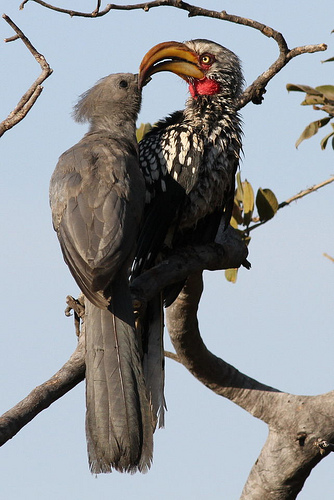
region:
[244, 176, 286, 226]
leaf on a tree branch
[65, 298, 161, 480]
bird tail feather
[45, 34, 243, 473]
two birds together in a tree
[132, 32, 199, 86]
yellow bird beak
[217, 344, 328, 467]
brown tree bark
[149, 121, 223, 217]
black and white spotted bird feathers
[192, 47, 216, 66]
yellow bird eye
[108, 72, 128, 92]
black bird eye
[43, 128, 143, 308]
grey bird wings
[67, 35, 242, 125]
two birds touching beaks in a tree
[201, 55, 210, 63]
yellow eye on bigger bird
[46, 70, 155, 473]
grey baby bird with long tail feathers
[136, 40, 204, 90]
crooked orange beak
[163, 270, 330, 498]
large tree branch on the right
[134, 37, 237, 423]
black and white large bird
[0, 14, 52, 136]
small crooked branch in the upper left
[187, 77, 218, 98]
red crop on larger bird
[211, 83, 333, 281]
branch with leaves on the right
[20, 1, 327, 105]
long, skinny tree branch on the top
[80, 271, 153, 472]
long grey tail feathers of baby bird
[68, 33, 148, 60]
the sky is blue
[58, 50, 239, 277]
the birds are perched on the tree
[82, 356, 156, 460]
the tail feathers are grey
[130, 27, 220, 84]
the beak is curved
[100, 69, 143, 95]
the eye is black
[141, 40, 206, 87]
the beak is brown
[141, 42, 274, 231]
the bird is scary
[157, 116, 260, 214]
the bird has white spots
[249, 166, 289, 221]
the leaves are green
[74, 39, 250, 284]
the birds are close together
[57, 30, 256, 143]
a bird feeding their young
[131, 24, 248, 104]
a bird with a long beak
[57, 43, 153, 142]
a baby bird eating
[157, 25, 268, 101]
a bird with red around its neck and eye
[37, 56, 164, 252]
a grey baby bird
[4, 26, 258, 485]
two birds sitting in a tree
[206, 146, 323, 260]
green leaves on a tree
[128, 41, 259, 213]
a bird with black and white feathers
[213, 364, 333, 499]
a large tree limb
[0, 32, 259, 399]
two birds sitting on a tree branch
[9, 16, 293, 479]
two birds in a tree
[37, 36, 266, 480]
two birds hanging out on a branch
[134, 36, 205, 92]
the curved beak of the colorful bird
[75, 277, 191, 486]
the bird's tail feathers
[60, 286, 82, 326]
a claw gripping the branch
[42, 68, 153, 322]
the younger bird being fed by its mom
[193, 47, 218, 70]
the bright yellow eye of the bird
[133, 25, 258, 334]
the bird with black and white spotted feathers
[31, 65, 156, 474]
the grey bird with a black eye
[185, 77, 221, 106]
the red spot under the bird's beak